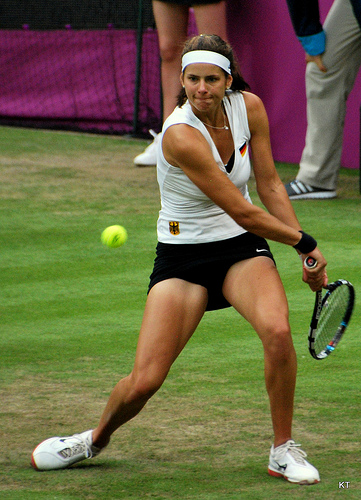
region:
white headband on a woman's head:
[180, 51, 232, 74]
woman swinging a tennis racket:
[30, 33, 356, 483]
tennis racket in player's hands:
[305, 254, 356, 360]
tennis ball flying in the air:
[100, 225, 127, 247]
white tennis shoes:
[32, 429, 320, 484]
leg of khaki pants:
[295, 0, 357, 190]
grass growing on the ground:
[0, 127, 359, 498]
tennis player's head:
[174, 34, 232, 111]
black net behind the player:
[1, 1, 167, 137]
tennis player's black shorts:
[146, 230, 275, 310]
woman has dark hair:
[149, 13, 236, 82]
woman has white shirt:
[143, 108, 287, 261]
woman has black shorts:
[106, 239, 289, 295]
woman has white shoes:
[268, 445, 319, 486]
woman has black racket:
[301, 295, 360, 369]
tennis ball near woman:
[88, 215, 155, 253]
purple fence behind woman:
[0, 31, 135, 120]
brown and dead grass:
[26, 366, 250, 465]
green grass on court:
[31, 225, 108, 308]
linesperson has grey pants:
[308, 11, 352, 216]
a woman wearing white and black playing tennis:
[84, 23, 340, 406]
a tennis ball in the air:
[95, 220, 133, 255]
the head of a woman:
[172, 24, 235, 111]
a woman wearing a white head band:
[175, 27, 233, 115]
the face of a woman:
[184, 68, 229, 113]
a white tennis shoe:
[264, 444, 331, 489]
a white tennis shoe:
[33, 430, 99, 476]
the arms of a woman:
[176, 114, 304, 239]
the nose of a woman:
[195, 81, 209, 100]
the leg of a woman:
[241, 268, 304, 441]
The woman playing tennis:
[0, 0, 359, 499]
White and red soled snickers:
[27, 431, 321, 486]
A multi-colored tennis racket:
[309, 253, 355, 362]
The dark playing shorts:
[147, 230, 275, 309]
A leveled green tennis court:
[0, 126, 359, 498]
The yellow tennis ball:
[100, 225, 127, 246]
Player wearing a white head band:
[181, 33, 248, 114]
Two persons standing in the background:
[133, 0, 359, 201]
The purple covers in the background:
[0, 0, 358, 169]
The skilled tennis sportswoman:
[32, 35, 319, 486]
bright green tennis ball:
[96, 221, 132, 251]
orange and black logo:
[166, 219, 180, 236]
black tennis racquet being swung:
[303, 249, 357, 361]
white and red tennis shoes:
[264, 438, 320, 484]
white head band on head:
[178, 48, 234, 82]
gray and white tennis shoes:
[277, 174, 335, 199]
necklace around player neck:
[192, 112, 231, 131]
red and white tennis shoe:
[27, 431, 107, 474]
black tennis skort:
[148, 228, 285, 314]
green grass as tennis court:
[0, 124, 359, 495]